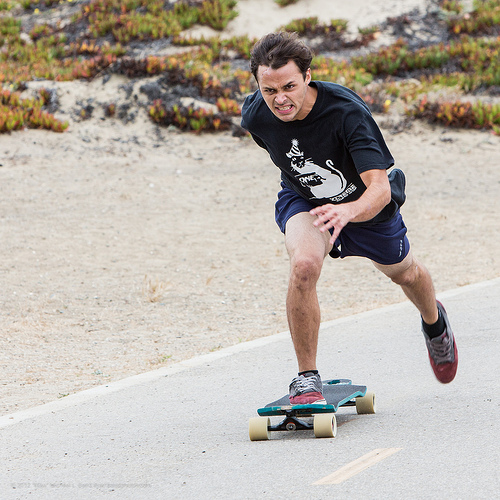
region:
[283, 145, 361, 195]
A MOUSE IS PRINTED ON THE SHIRT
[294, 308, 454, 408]
MAN IS WEARING RED SHOES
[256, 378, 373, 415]
EDGE OF SKATE BOARD IS GREEN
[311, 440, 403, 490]
DASH ON ROAD IS WHITE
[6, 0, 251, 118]
RED AND GREEN FOLIAGE IS IN THE BACKGROUND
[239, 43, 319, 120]
MANS TEETH ARE SHOWING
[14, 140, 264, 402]
BROWN GRAVEL LINES THE ROAD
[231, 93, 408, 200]
MAN IS WEARING A BLACK SHIRT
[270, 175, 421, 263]
MAN IS WEARING BLUE SHORTS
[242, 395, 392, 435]
SKATE BOARD HAS WHITE TIRES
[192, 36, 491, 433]
this is a person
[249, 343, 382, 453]
this is a skate board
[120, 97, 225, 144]
some plants in the ground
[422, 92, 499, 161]
some plants in the ground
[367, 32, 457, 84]
some plants in the ground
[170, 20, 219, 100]
some plants in the ground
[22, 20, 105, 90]
some plants in the ground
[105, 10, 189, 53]
some plants in the ground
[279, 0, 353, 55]
some plants in the ground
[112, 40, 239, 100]
some plants in the ground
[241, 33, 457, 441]
man skatingboarding on the road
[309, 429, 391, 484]
white dash painted on the road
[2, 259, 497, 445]
white line painted on the road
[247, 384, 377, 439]
white wheels on the skateboard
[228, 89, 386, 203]
black shirt with white logo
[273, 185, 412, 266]
blue shorts of skateboarder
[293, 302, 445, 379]
black socks of skateboarder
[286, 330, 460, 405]
gray and red shoes of skateboarder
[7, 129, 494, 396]
dirt patch by the roadside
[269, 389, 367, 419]
blue edges of the skateboard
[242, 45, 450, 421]
Man on a skateboard.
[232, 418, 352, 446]
The wheels are light yellow.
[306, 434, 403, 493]
Yellow line on the road.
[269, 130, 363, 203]
Decal on the shirt.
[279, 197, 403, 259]
The shorts are dark blue.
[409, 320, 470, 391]
The shoe is grey and red.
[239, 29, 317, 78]
The man has dark hair.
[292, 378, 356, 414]
Top of the skateboard is black.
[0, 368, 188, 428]
White line on the side of the road.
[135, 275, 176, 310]
Dry grass in the dirt.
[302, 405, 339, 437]
wheel on the skateboard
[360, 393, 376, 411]
wheel on the skateboard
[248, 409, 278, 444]
wheel on the skateboard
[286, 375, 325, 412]
shoe on the man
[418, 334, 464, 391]
shoe on the man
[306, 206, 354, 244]
hand of the man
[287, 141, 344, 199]
graphic on the shirt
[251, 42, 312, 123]
head of the man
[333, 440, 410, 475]
dash on the road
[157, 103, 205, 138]
plant on side of road